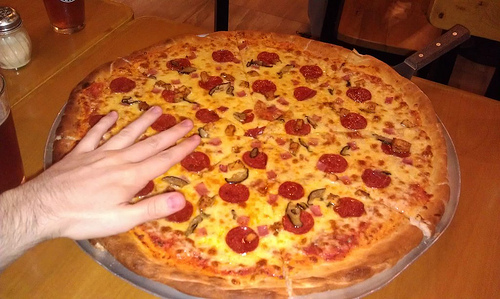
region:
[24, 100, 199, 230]
hand touching the pizza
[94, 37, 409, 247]
pepperoni slices on the pizza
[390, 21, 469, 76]
handle of the spatula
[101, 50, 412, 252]
cheese on the pizza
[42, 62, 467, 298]
pan the pizza is on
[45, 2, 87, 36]
drinking glass on the table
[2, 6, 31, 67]
parmesian cheese shaker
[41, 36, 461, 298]
crust of the pizza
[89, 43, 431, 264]
sauce on the pizza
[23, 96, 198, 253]
a hand on pizza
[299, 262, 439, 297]
a piece of brown crust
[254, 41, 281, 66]
a red peperioni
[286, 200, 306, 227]
a slice of mushroom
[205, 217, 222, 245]
yellow melted cheese on pizza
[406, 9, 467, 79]
a wooden handle of server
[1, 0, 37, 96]
a clear shaker with silver lid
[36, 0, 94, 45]
a clear glass with brown liquid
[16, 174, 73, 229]
black hair on arm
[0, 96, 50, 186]
a clear glass almost full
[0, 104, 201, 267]
Persons hairy wrist and hand.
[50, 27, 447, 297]
Pizza with pepperoni and another topping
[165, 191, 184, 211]
Finger nail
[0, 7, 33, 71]
Glass salt shaker with metal lid.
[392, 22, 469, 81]
Wooden handle of utensil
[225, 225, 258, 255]
Slice of pepperoni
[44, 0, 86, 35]
Bottom of glass with drink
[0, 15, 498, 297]
pepperoni pizza on a wooden table.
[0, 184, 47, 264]
Black hair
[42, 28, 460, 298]
Pizza on a thin metal tray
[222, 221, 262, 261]
a pepperoni on pizza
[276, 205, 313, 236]
a pepperoni on pizza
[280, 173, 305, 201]
a pepperoni on pizza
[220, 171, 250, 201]
a pepperoni on pizza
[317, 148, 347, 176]
a pepperoni on pizza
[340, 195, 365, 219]
a pepperoni on pizza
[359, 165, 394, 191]
a pepperoni on pizza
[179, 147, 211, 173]
a pepperoni on pizza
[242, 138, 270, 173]
a pepperoni on pizza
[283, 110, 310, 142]
a pepperoni on pizza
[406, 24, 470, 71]
Wooden handle of a utensil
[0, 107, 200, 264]
A man's hand hovering over a pizza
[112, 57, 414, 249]
Pepperoni slices topping a pizza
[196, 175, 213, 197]
Bit of ham on a pizza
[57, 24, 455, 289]
A pizza on the table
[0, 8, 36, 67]
A shaker of Parmesan cheese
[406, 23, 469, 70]
Handle of a utensil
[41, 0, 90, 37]
Bottom of a glass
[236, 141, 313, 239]
melted cheese on the pizza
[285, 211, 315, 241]
pepperoni on the pizza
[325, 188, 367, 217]
peperoni on the pizza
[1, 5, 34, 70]
shaker container of parmesan cheese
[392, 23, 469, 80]
brown handle of a utensil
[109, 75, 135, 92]
piece of pepperoni on a pizza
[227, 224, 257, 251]
piece of pepperoni on a pizza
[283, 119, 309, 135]
piece of pepperoni on a pizza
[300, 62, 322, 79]
piece of pepperoni on a pizza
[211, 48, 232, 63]
piece of pepperoni on a pizza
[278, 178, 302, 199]
piece of pepperoni on a pizza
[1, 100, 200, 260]
hand on top of a pizza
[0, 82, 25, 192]
glass of beer